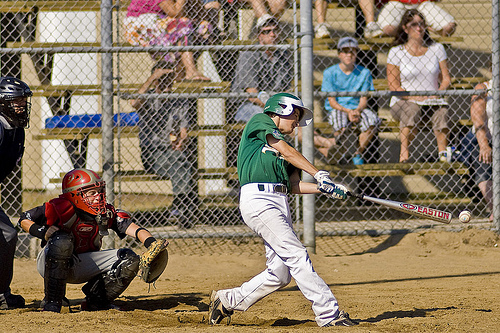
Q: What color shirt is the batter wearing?
A: Green.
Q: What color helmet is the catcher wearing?
A: Red.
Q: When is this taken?
A: Daytime.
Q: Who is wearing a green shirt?
A: The batter.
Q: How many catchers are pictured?
A: One.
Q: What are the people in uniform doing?
A: Playing baseball.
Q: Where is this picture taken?
A: At a baseball diamond.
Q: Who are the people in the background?
A: Spectators.